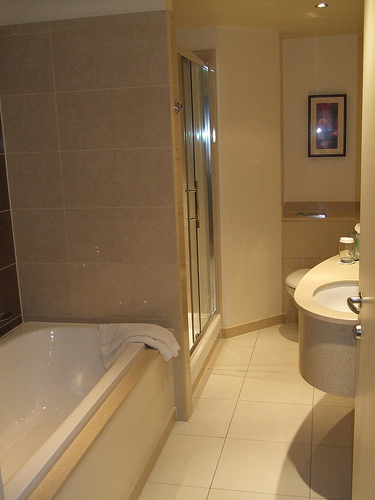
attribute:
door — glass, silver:
[179, 57, 217, 353]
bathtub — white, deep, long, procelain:
[1, 320, 176, 499]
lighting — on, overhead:
[317, 2, 328, 11]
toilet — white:
[285, 269, 313, 343]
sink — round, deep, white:
[312, 280, 358, 314]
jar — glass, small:
[339, 238, 357, 264]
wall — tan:
[0, 0, 186, 420]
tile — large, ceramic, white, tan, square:
[139, 320, 354, 499]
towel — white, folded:
[96, 324, 180, 373]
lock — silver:
[352, 325, 362, 339]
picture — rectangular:
[308, 94, 346, 157]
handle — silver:
[346, 294, 363, 314]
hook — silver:
[174, 100, 186, 112]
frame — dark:
[310, 95, 348, 157]